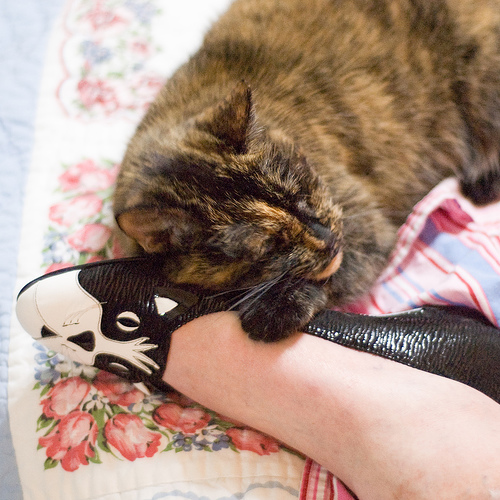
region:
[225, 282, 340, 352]
A cat paw.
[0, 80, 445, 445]
The cat is resting its head on a person's foot.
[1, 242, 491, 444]
The person is wearing a black and white cat shoe.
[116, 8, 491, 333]
The cat is multicolored.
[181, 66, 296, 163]
An ear on a cat.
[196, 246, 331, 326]
Whiskers on a cat.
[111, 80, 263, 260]
A cat has two ears.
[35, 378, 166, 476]
A picture of roses on the bedspread.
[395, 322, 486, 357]
Part of the shoe is black.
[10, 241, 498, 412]
The woman is wearing a slip on shoe without a sock.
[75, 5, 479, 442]
Kitty sleeping on a foot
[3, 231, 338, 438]
Kitty shoe on foot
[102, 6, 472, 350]
Pretty calico kitty sleeping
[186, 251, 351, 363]
Kitty paw resting on shoe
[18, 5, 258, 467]
Flowery pattern on bedspread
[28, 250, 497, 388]
Brown and white leather shoe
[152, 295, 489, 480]
Pale skin foot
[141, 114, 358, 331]
Kitty chin resting on paw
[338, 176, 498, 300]
Striped pattern on bedspread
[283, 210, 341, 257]
Gold and brown kitty nose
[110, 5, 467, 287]
a cat sleeping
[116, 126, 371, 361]
a cat sleeping on a woman's shoe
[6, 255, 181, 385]
tip of woman's shoe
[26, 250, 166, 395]
a shoe with a cat face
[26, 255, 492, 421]
woman wearing a shoe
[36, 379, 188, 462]
printed roses on a blanket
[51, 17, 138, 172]
white blanket with printed floral patterns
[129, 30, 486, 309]
a tabby cat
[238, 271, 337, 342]
a cat's paw touching a woman's shoe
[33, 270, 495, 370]
a white and black shoe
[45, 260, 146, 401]
Cat on toe of shoe.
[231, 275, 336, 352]
Cat has dark paw.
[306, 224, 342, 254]
Cat has dark nose.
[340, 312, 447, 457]
Black shoe on person's foot.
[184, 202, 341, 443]
Cat resting head on person's foot.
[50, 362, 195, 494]
Flower print on sheet.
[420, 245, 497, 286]
Stripe pattern on sheet.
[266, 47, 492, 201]
Cat is light brown and dark brown.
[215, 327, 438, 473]
Person has white foot.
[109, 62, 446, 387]
Cat is laying on bed.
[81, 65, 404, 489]
cat's head on the feet